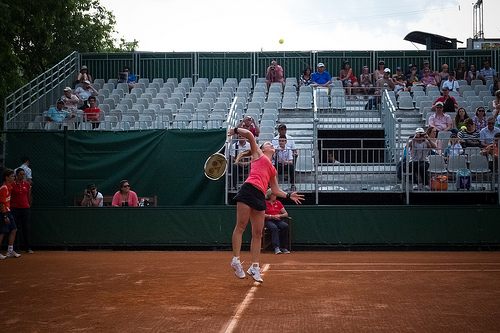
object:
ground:
[441, 150, 453, 165]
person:
[9, 167, 34, 254]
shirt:
[12, 181, 31, 208]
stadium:
[0, 0, 500, 333]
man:
[310, 62, 331, 87]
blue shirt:
[310, 71, 332, 84]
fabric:
[85, 47, 500, 78]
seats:
[28, 77, 298, 129]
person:
[77, 65, 93, 86]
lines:
[220, 261, 500, 332]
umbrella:
[233, 0, 260, 25]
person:
[409, 127, 437, 191]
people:
[265, 56, 500, 91]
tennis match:
[4, 128, 500, 333]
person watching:
[83, 95, 101, 129]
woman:
[453, 107, 472, 129]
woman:
[374, 59, 385, 80]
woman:
[472, 107, 489, 134]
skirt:
[233, 182, 268, 212]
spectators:
[394, 58, 498, 190]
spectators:
[266, 59, 398, 110]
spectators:
[45, 80, 101, 131]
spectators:
[74, 64, 138, 85]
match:
[0, 164, 500, 333]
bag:
[429, 175, 448, 192]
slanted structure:
[404, 31, 465, 51]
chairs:
[121, 77, 281, 130]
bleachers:
[28, 69, 500, 182]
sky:
[0, 0, 500, 52]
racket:
[204, 130, 234, 181]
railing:
[222, 140, 495, 203]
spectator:
[273, 135, 295, 185]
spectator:
[271, 124, 298, 166]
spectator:
[444, 133, 465, 168]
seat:
[330, 92, 346, 109]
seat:
[298, 92, 312, 109]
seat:
[258, 126, 275, 142]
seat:
[267, 91, 280, 103]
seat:
[399, 96, 415, 109]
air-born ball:
[278, 39, 284, 45]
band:
[286, 193, 290, 199]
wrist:
[285, 192, 290, 199]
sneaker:
[230, 261, 246, 279]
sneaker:
[247, 266, 264, 282]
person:
[263, 188, 291, 256]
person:
[204, 127, 306, 283]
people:
[80, 182, 103, 206]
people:
[111, 179, 138, 207]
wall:
[4, 131, 225, 213]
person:
[428, 100, 458, 134]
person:
[73, 80, 99, 108]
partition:
[0, 206, 500, 250]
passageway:
[316, 129, 386, 171]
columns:
[462, 3, 478, 41]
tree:
[0, 0, 139, 70]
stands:
[0, 45, 500, 250]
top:
[244, 154, 278, 195]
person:
[266, 60, 285, 89]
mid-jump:
[226, 265, 262, 296]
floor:
[414, 189, 457, 192]